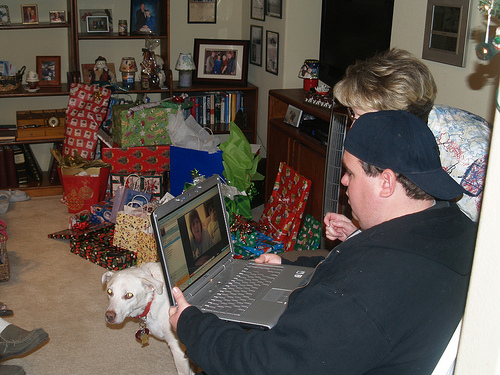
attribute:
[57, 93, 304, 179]
presents — wrapped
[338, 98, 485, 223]
cap — black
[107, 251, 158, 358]
collar — red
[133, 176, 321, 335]
laptop — open, silver, on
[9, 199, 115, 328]
carpet — beige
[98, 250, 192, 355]
dog — white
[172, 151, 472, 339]
man — sitting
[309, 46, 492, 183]
woman — looking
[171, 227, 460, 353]
sweatshirt — black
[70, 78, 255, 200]
gifts — wrapped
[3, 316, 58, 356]
shoe — brown, gray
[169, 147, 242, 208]
bag — blue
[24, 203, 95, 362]
floor — carpet